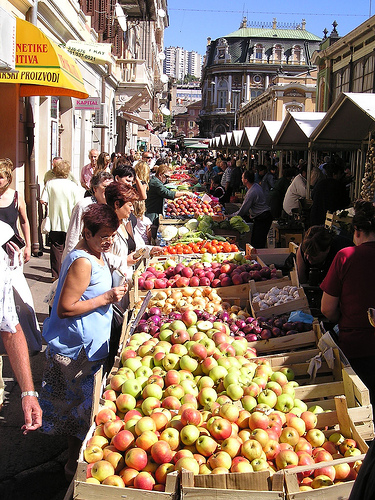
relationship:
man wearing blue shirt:
[37, 203, 130, 477] [48, 240, 109, 352]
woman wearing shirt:
[296, 224, 356, 307] [295, 227, 374, 349]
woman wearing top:
[0, 155, 45, 265] [1, 182, 26, 257]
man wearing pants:
[226, 158, 286, 268] [250, 207, 273, 248]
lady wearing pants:
[39, 157, 88, 289] [47, 231, 66, 283]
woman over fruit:
[296, 225, 354, 278] [222, 255, 297, 380]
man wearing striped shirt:
[215, 154, 240, 209] [220, 167, 232, 188]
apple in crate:
[120, 347, 218, 419] [123, 352, 356, 390]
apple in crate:
[206, 247, 238, 263] [123, 352, 356, 390]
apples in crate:
[133, 251, 295, 289] [134, 257, 305, 302]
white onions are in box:
[252, 283, 300, 307] [246, 279, 310, 314]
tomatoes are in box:
[223, 244, 229, 253] [164, 241, 245, 253]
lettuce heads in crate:
[184, 215, 247, 236] [165, 216, 283, 243]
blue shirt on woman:
[42, 249, 114, 362] [53, 203, 119, 374]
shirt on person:
[319, 241, 374, 313] [323, 201, 374, 350]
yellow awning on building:
[0, 16, 90, 99] [0, 12, 90, 256]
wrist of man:
[8, 370, 44, 413] [1, 250, 129, 494]